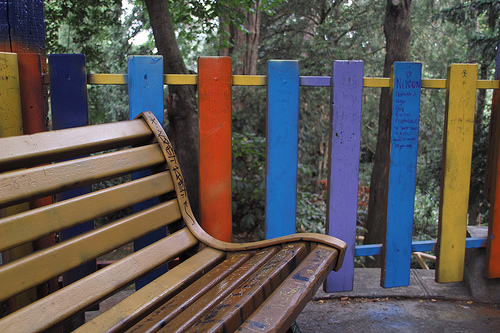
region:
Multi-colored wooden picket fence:
[2, 48, 499, 290]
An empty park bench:
[1, 111, 351, 331]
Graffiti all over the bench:
[141, 111, 335, 331]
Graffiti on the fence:
[391, 63, 423, 155]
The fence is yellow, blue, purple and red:
[5, 46, 498, 288]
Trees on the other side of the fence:
[2, 10, 496, 264]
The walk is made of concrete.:
[86, 262, 496, 331]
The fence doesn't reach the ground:
[1, 49, 498, 303]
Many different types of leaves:
[36, 9, 498, 258]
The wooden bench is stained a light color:
[2, 110, 349, 332]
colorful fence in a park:
[57, 38, 480, 330]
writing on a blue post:
[387, 68, 423, 158]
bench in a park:
[4, 113, 358, 331]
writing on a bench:
[155, 125, 193, 211]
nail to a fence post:
[139, 66, 154, 86]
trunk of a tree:
[376, 2, 413, 279]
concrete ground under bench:
[328, 280, 480, 330]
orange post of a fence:
[192, 46, 240, 238]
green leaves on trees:
[54, 1, 115, 51]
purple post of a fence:
[326, 50, 363, 305]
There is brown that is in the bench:
[255, 245, 271, 290]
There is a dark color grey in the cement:
[351, 291, 363, 330]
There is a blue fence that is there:
[386, 174, 414, 264]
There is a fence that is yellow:
[441, 149, 475, 253]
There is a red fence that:
[191, 92, 228, 186]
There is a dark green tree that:
[331, 23, 346, 63]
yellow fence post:
[432, 51, 482, 288]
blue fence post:
[378, 57, 429, 293]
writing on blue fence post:
[392, 71, 422, 162]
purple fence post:
[324, 49, 371, 292]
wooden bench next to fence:
[2, 107, 354, 327]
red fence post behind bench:
[189, 50, 242, 232]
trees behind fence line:
[74, 4, 487, 233]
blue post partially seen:
[124, 46, 166, 121]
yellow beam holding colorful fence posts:
[77, 64, 492, 96]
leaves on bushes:
[236, 126, 266, 231]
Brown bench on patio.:
[28, 149, 158, 320]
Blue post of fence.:
[397, 65, 418, 288]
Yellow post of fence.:
[452, 63, 477, 287]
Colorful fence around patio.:
[159, 55, 484, 220]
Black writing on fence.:
[147, 117, 202, 230]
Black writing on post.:
[394, 72, 416, 167]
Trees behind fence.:
[180, 13, 426, 60]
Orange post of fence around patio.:
[201, 60, 227, 191]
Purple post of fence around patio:
[335, 65, 360, 251]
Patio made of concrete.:
[348, 301, 449, 331]